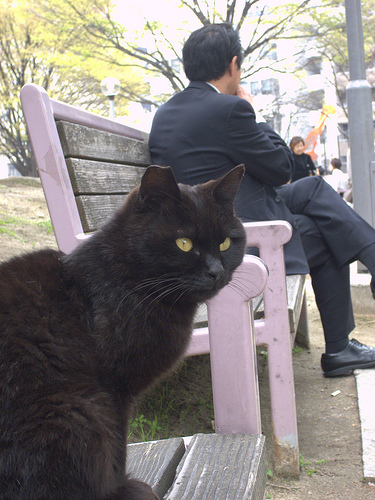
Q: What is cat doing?
A: Sitting.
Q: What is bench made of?
A: Wood.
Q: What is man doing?
A: Crossing legs.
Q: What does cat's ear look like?
A: Missing a piece.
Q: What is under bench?
A: Grass.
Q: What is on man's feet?
A: Shoes.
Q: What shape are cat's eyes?
A: Circle.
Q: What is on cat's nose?
A: Whiskers.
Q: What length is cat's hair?
A: Short.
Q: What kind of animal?
A: Cat.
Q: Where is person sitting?
A: Bench.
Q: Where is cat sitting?
A: Bench.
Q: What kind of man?
A: Businessman.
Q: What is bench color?
A: Pink.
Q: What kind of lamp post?
A: Metal.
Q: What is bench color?
A: Pink.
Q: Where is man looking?
A: Away.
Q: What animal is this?
A: Cat.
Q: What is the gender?
A: Male.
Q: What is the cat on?
A: Bench.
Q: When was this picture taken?
A: Daytime.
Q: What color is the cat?
A: Black.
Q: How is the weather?
A: Clear.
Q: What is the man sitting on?
A: A bench.